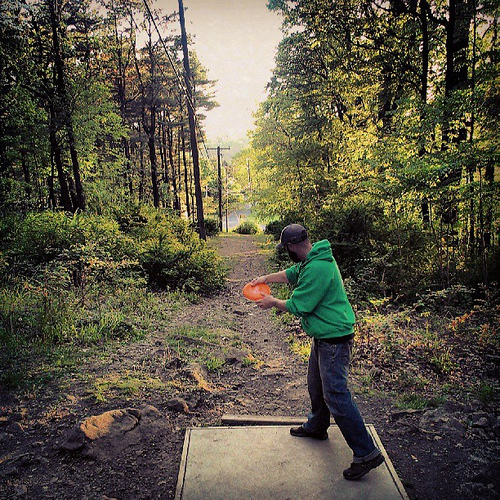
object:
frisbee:
[238, 281, 273, 304]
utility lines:
[138, 1, 211, 164]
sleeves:
[284, 258, 306, 287]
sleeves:
[283, 268, 328, 318]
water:
[215, 208, 267, 233]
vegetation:
[354, 194, 452, 292]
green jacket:
[280, 237, 357, 342]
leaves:
[79, 107, 117, 147]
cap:
[274, 224, 309, 251]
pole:
[215, 148, 224, 234]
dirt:
[0, 237, 499, 499]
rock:
[158, 397, 189, 409]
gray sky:
[22, 0, 499, 149]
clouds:
[18, 0, 497, 141]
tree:
[263, 29, 338, 228]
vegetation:
[24, 207, 141, 289]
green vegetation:
[136, 217, 227, 295]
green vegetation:
[472, 380, 494, 406]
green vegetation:
[232, 220, 257, 234]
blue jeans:
[301, 333, 381, 462]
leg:
[314, 336, 380, 463]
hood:
[305, 238, 336, 265]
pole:
[174, 1, 208, 244]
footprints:
[77, 409, 138, 441]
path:
[0, 231, 499, 499]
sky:
[20, 0, 499, 165]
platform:
[175, 422, 409, 499]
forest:
[0, 1, 499, 391]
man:
[249, 224, 384, 483]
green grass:
[240, 353, 257, 369]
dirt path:
[0, 234, 499, 499]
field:
[0, 226, 499, 498]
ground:
[0, 232, 499, 499]